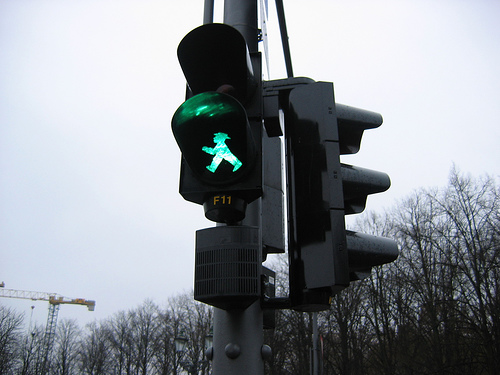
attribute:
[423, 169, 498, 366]
tree — dry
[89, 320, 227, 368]
tree — dry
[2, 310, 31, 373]
tree — dry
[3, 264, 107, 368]
crane — big, construction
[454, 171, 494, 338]
tree — dry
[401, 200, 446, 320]
tree — dry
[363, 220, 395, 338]
tree — dry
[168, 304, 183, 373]
tree — dry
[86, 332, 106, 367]
tree — dry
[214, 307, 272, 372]
pole — gray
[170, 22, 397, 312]
traffic light — metal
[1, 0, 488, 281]
sky — overcast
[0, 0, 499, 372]
sky — gray, cloudy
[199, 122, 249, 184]
man — green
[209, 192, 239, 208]
f11 — yellow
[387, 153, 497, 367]
tree — dry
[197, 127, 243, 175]
symbol — walking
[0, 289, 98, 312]
crane — yellow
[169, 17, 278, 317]
light — shiney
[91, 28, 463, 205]
sky — dreary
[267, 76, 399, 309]
box — dark